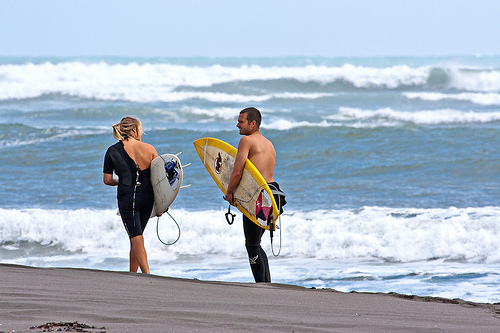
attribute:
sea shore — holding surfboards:
[8, 250, 426, 328]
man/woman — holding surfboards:
[95, 101, 289, 290]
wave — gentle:
[341, 211, 466, 261]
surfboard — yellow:
[191, 134, 287, 232]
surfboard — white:
[146, 151, 189, 223]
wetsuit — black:
[104, 150, 154, 236]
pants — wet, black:
[241, 180, 293, 281]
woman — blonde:
[96, 115, 166, 270]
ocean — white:
[7, 58, 496, 254]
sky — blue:
[309, 11, 498, 42]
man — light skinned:
[222, 99, 291, 296]